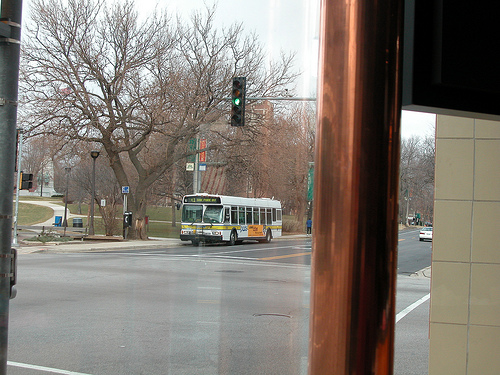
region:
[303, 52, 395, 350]
copper colored pole in window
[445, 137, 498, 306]
tan colored tile wall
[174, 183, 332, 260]
commuter bus in transit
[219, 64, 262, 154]
black traffic light in the middle of intersection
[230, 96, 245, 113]
light green light on traffic light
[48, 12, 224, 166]
a treet with no leaves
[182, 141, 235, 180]
a green and red banner hanging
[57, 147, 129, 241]
matching round street lights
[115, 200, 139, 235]
public phone box on corner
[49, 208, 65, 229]
a baby blue metal trashcan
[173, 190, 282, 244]
large white bus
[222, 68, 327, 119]
traffic light with green light on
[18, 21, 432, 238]
a buch of dry trees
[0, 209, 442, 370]
grey large pavement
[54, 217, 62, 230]
small blue trash can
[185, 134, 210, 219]
orange and green sign in a pole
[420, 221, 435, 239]
car in the street far away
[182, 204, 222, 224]
two windshields in the front of white bus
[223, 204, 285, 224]
lot of windows in the left side of a white bus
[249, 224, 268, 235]
orange signboard in left side of a white bus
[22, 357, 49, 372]
white line on road.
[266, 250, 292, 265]
yellow line on road.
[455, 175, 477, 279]
tile on the wall.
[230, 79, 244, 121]
stop light on pole.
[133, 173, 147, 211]
trunk of the tree.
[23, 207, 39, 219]
grass on the ground.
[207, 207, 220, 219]
windshield of the bus.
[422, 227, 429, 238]
white car in the road.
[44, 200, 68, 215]
sidewalk through the park.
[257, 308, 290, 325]
manhole cover on road.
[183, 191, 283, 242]
yellow and white bud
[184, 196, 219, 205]
destination sign in bus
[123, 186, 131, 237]
phone booth on pole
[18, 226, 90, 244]
wooden bench by sidewalk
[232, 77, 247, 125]
black electronic stop sign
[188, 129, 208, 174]
banners on metal pole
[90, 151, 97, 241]
grey metal street lamp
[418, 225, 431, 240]
white car on street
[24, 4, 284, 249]
tree with no leaves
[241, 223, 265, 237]
sign on side of bus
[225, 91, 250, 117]
glowing green on traffic light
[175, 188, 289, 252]
bus on side of street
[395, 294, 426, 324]
white line in road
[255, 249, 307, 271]
yellow line in road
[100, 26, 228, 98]
tree branches with no leaves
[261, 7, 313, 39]
cloud cover in sky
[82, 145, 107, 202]
light on black pole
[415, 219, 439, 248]
back of white car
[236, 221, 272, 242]
advertisement on side of bus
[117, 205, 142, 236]
public phone on pole